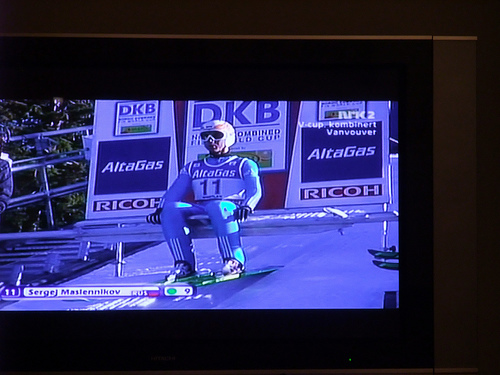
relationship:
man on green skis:
[146, 118, 263, 280] [165, 256, 281, 285]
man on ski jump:
[146, 118, 263, 280] [1, 206, 397, 310]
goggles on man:
[199, 130, 224, 140] [146, 118, 263, 280]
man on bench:
[146, 118, 263, 280] [86, 115, 398, 240]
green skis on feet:
[93, 256, 274, 307] [157, 251, 242, 277]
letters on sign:
[96, 183, 386, 206] [298, 182, 384, 200]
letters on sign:
[96, 183, 386, 206] [91, 195, 158, 212]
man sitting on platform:
[143, 118, 263, 285] [49, 141, 398, 263]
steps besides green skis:
[1, 147, 129, 299] [165, 256, 281, 285]